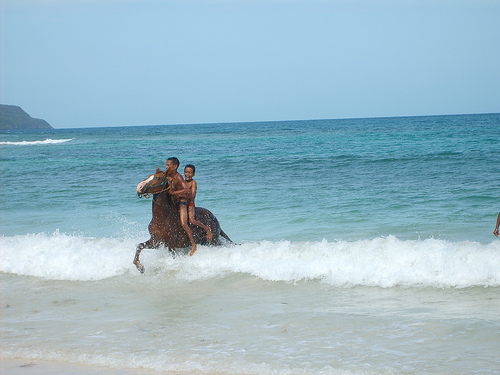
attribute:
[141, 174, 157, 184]
spot — small, white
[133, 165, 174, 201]
head — horse's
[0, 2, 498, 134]
sky — blue , clear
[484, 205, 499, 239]
arm — person's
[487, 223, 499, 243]
hand — person's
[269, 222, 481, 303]
wave — shallow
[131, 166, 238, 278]
horse — brown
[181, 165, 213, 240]
boy — young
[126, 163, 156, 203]
head — brown, white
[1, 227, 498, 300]
wave — white, foamy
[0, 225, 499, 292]
surf — crashing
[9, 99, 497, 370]
wave — crashing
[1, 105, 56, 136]
cliff — brown, large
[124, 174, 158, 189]
fur — white 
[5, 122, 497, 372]
ocean water — clear , blue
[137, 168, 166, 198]
face — white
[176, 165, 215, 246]
kid — shirtless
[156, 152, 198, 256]
kid — shirtless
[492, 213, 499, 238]
arm — person's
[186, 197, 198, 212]
suit — bathing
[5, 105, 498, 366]
water — shallow spread, ocean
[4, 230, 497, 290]
foam — thick, white, sea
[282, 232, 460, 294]
foam — white